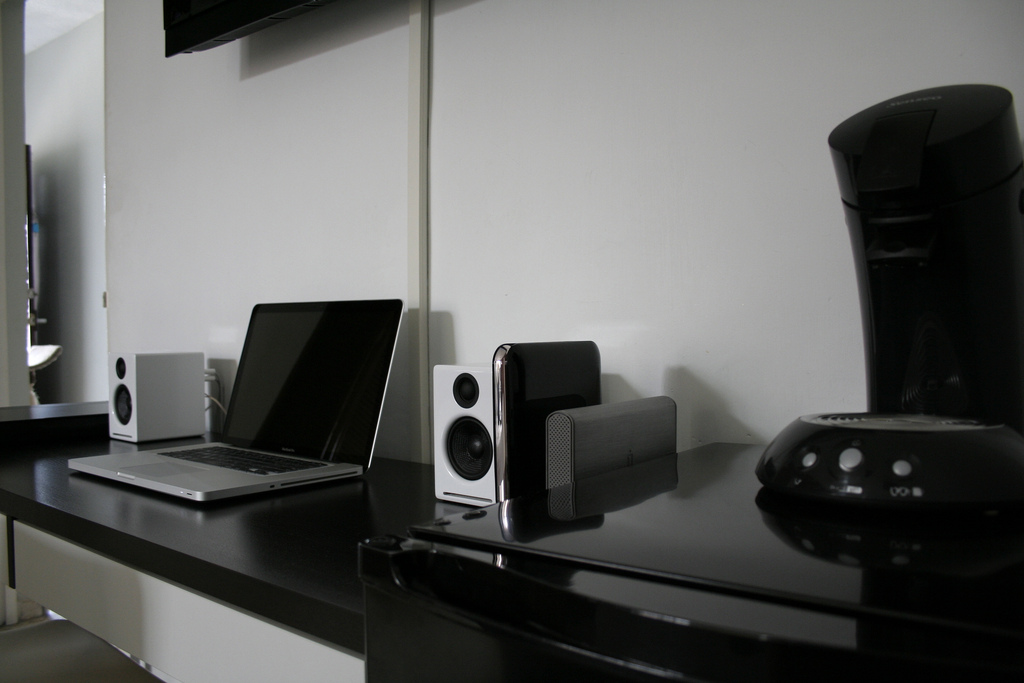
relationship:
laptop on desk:
[199, 259, 412, 508] [211, 516, 331, 616]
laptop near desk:
[199, 259, 412, 508] [211, 516, 331, 616]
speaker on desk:
[408, 346, 526, 511] [211, 516, 331, 616]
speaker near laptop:
[408, 346, 526, 511] [199, 259, 412, 508]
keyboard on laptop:
[183, 431, 274, 481] [199, 259, 412, 508]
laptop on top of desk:
[199, 259, 412, 508] [211, 516, 331, 616]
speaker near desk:
[408, 346, 526, 511] [211, 516, 331, 616]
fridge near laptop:
[418, 544, 670, 663] [199, 259, 412, 508]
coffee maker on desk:
[795, 104, 1020, 536] [211, 516, 331, 616]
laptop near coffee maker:
[199, 259, 412, 508] [795, 104, 1020, 536]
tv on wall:
[157, 9, 277, 53] [468, 23, 691, 201]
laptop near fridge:
[199, 259, 412, 508] [418, 544, 670, 663]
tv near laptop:
[157, 9, 277, 53] [199, 259, 412, 508]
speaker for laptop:
[408, 346, 526, 511] [199, 259, 412, 508]